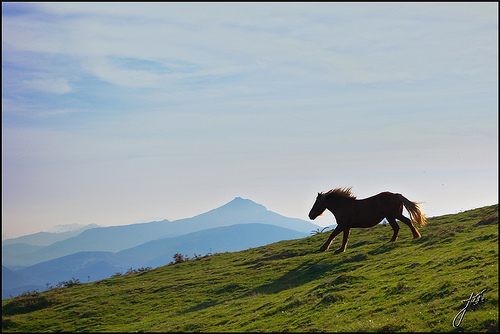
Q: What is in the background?
A: Mountains.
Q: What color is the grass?
A: Green.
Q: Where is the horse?
A: In a field.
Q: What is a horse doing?
A: Running.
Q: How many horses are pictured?
A: One.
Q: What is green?
A: Grass.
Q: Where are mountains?
A: In the distance.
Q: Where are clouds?
A: In the sky.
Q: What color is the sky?
A: Blue.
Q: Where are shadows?
A: On the grass.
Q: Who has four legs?
A: The horse.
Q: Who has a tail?
A: The horse.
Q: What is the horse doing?
A: Running.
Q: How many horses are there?
A: One.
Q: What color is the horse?
A: Brown.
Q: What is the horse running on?
A: Grass.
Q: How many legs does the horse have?
A: Four.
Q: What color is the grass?
A: Green.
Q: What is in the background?
A: Mountains.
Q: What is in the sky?
A: Clouds.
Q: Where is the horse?
A: Meadow.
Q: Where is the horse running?
A: On a grassy field.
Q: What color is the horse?
A: Brown.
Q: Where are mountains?
A: In the distance.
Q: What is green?
A: Grass.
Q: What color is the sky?
A: Blue.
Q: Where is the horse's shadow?
A: On the grass.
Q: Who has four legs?
A: The horse.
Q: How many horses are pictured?
A: One.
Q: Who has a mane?
A: A horse.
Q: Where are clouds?
A: In the sky.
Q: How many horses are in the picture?
A: 1.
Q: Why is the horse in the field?
A: Galloping.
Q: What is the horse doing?
A: Running free on the land.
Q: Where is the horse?
A: Hill.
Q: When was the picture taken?
A: During the daytime.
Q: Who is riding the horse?
A: Nobody.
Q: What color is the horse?
A: Brown.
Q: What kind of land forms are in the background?
A: Hills.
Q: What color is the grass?
A: Green.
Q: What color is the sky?
A: Blue.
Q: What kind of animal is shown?
A: Horse.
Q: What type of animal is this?
A: A horse.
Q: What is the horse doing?
A: Running.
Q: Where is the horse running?
A: Down the hill.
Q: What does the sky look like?
A: Overcast.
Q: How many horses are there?
A: 1.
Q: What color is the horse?
A: Brown.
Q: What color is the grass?
A: Green.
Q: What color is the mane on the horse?
A: Reddish brown.